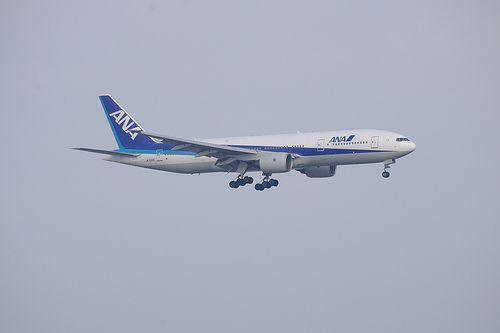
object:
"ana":
[328, 135, 348, 143]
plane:
[63, 91, 420, 193]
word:
[108, 109, 144, 141]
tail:
[90, 91, 158, 150]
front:
[327, 127, 422, 167]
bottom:
[149, 150, 399, 180]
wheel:
[270, 178, 280, 188]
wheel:
[262, 180, 271, 189]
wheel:
[246, 175, 255, 184]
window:
[365, 140, 369, 144]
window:
[332, 142, 334, 146]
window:
[340, 142, 343, 146]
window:
[298, 144, 302, 149]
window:
[354, 141, 357, 145]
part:
[329, 130, 360, 165]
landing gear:
[380, 170, 392, 180]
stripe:
[154, 143, 398, 157]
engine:
[302, 165, 339, 180]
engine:
[257, 152, 294, 174]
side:
[262, 131, 373, 164]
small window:
[332, 142, 335, 146]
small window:
[302, 144, 306, 148]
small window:
[291, 145, 295, 149]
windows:
[325, 142, 330, 147]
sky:
[2, 1, 499, 92]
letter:
[328, 135, 336, 143]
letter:
[336, 135, 342, 142]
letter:
[339, 135, 347, 143]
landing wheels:
[227, 180, 241, 190]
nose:
[406, 140, 419, 154]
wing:
[134, 129, 259, 157]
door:
[315, 137, 327, 152]